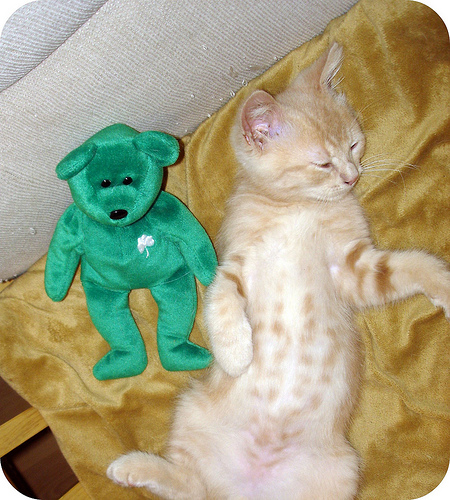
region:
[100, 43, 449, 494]
a kitten laying on the couch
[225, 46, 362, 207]
the very cute face of the little kitty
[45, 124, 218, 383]
a little green bear laying by the kitten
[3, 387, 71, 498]
some wood under the blanket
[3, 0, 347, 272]
the arm of the couch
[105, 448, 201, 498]
the paw of the kitten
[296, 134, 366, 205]
the face of the kitten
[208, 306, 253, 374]
another kitten paw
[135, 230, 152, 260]
a white tree on the bear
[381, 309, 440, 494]
part of the blanket of the kitten is on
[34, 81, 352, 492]
orange kitten next to green bear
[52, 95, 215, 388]
green bear with white flower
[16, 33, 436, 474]
teddy bear and orange kitten on yellow fabric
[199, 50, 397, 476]
orange kitten laying on back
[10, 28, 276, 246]
green bear on beige couch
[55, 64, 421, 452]
bear and kitten next to each other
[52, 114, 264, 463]
green bear on orange fabric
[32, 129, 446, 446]
kitten not looking at bear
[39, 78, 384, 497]
kitten not playing with bear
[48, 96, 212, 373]
green stuffed teddy bear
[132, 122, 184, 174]
the green ear of a teddy bear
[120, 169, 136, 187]
the eye of a teddy bear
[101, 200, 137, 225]
the nose of a teddy bear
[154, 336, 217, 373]
the foot of a teddy bear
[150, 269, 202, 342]
the leg of a teddy bear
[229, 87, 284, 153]
the ear of a cat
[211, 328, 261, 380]
the paw of a cat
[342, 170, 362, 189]
the nose of a cat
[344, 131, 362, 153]
the eye of a cat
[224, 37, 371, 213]
the head of a cat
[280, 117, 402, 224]
This cat has an extremely serious expression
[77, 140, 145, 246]
This teddy bear has an extremely sad expression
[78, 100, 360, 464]
This photo was taken in the living room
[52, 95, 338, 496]
This photo was taken by Jeffrey Zane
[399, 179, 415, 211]
This blanket is a very, very deep gold color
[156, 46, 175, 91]
The upholstery has a light beige color to it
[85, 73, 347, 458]
This photo was taken around noon time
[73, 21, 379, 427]
This photo was taken in the city of Boston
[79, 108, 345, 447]
This photo was taken in the state of Massachusetts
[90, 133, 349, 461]
This photo received an award for its presentation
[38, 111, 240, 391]
green teddy bear on blanket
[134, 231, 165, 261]
white flower on teddy bear chest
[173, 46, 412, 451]
young cat laying on back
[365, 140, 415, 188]
white whiskers on cat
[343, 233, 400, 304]
orange stripes on cat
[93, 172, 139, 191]
black eyes on toy face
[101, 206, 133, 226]
black nose on face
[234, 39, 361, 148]
ears on cat head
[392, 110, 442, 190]
wrinkle in brown blanket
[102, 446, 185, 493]
back paw on cat